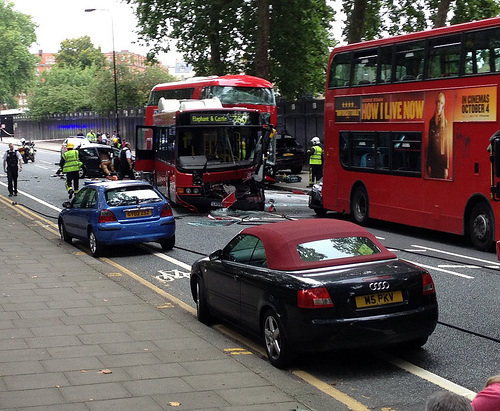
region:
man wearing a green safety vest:
[51, 135, 86, 190]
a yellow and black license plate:
[356, 287, 408, 307]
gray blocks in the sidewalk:
[44, 289, 149, 409]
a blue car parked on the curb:
[70, 176, 172, 256]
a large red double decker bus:
[323, 36, 488, 241]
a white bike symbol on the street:
[144, 261, 186, 285]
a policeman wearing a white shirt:
[4, 147, 30, 197]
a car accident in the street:
[59, 125, 139, 176]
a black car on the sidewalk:
[283, 129, 308, 172]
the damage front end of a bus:
[194, 168, 274, 208]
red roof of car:
[251, 219, 360, 235]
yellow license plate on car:
[349, 288, 414, 316]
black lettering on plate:
[356, 292, 401, 303]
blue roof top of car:
[86, 179, 151, 187]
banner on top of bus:
[183, 110, 263, 125]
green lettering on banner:
[188, 115, 237, 122]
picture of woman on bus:
[428, 92, 453, 182]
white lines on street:
[406, 240, 498, 279]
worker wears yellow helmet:
[62, 140, 78, 152]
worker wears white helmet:
[307, 135, 325, 144]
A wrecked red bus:
[146, 96, 263, 208]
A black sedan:
[182, 202, 430, 374]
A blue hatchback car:
[55, 176, 180, 262]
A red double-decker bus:
[321, 3, 499, 250]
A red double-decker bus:
[141, 75, 281, 175]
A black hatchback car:
[272, 126, 299, 180]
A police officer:
[2, 140, 28, 198]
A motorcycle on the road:
[13, 130, 45, 166]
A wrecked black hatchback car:
[62, 140, 138, 177]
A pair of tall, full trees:
[129, 0, 321, 103]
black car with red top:
[200, 225, 431, 370]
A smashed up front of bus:
[165, 81, 290, 226]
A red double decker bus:
[310, 23, 497, 254]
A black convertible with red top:
[181, 210, 455, 388]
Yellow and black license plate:
[352, 289, 414, 309]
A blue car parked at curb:
[60, 179, 184, 269]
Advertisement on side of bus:
[331, 89, 496, 206]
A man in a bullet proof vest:
[3, 138, 28, 200]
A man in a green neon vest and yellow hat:
[49, 136, 92, 205]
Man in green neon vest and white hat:
[298, 133, 327, 190]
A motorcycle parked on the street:
[16, 123, 47, 168]